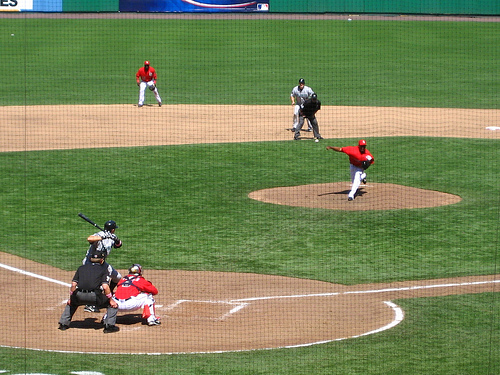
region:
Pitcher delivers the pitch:
[323, 132, 381, 204]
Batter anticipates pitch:
[71, 207, 120, 325]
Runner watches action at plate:
[282, 77, 332, 138]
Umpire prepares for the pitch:
[55, 248, 125, 333]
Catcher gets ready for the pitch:
[105, 265, 167, 330]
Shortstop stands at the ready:
[124, 54, 174, 109]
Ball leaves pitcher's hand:
[309, 135, 346, 158]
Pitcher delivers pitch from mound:
[248, 136, 461, 218]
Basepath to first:
[238, 268, 495, 305]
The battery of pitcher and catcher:
[111, 134, 380, 331]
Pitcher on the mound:
[325, 136, 380, 204]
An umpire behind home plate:
[57, 248, 126, 335]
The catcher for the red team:
[109, 262, 162, 325]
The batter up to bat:
[75, 210, 125, 253]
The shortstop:
[132, 58, 167, 108]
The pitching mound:
[248, 171, 461, 211]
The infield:
[0, 135, 498, 275]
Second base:
[485, 120, 497, 132]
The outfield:
[5, 11, 495, 72]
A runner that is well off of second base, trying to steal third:
[290, 76, 315, 116]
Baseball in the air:
[311, 135, 320, 146]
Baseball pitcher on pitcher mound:
[325, 135, 380, 203]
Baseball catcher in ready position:
[116, 262, 161, 334]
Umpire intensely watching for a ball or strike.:
[51, 257, 114, 338]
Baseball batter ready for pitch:
[69, 207, 124, 261]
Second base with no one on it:
[468, 109, 498, 145]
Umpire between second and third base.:
[298, 92, 328, 143]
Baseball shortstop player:
[129, 57, 170, 107]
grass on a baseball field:
[113, 172, 200, 217]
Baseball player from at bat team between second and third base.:
[278, 74, 311, 126]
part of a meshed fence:
[421, 65, 489, 147]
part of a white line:
[386, 297, 400, 319]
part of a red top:
[113, 270, 143, 295]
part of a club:
[71, 196, 96, 232]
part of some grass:
[191, 230, 254, 262]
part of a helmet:
[99, 209, 122, 233]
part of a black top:
[83, 268, 107, 296]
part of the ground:
[251, 292, 297, 335]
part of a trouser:
[96, 304, 121, 327]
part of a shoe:
[101, 319, 124, 339]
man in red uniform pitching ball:
[327, 138, 381, 203]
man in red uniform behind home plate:
[114, 264, 158, 330]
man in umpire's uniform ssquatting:
[54, 246, 121, 334]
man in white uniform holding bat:
[72, 207, 124, 255]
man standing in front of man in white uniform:
[292, 89, 325, 144]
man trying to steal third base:
[288, 72, 316, 135]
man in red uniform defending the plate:
[134, 57, 172, 110]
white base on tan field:
[484, 121, 497, 137]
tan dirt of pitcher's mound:
[242, 168, 466, 220]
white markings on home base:
[162, 278, 257, 331]